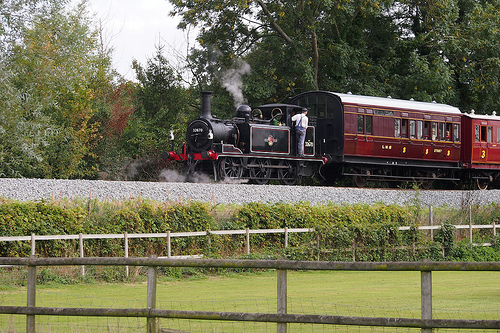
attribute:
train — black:
[178, 91, 290, 174]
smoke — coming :
[208, 46, 253, 101]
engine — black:
[181, 86, 327, 181]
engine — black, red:
[93, 42, 498, 254]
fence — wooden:
[0, 248, 498, 330]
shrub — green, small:
[1, 202, 83, 235]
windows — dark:
[354, 112, 375, 137]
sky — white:
[5, 0, 499, 81]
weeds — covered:
[0, 192, 499, 271]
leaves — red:
[112, 108, 129, 130]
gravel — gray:
[106, 176, 489, 216]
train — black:
[173, 91, 498, 184]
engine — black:
[182, 92, 322, 180]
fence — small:
[393, 252, 451, 317]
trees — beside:
[0, 25, 492, 189]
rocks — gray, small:
[2, 183, 491, 212]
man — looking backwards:
[288, 104, 318, 161]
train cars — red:
[288, 90, 498, 189]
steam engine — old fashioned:
[187, 65, 274, 156]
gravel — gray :
[123, 169, 498, 239]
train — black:
[120, 35, 435, 206]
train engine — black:
[201, 94, 318, 162]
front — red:
[174, 72, 394, 186]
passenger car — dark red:
[288, 87, 465, 187]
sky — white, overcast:
[48, 32, 189, 98]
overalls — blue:
[290, 118, 322, 161]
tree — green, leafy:
[21, 19, 160, 213]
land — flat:
[250, 264, 407, 309]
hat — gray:
[302, 103, 317, 116]